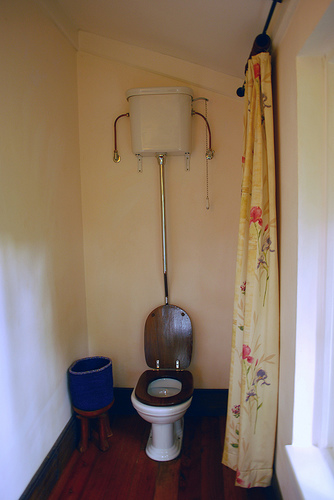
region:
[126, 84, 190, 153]
Toilet over head box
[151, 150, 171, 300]
Pipe connecting to toilet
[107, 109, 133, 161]
Pipes connecting to reservoir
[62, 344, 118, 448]
A stool with blue thing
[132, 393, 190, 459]
White porcelain toilet base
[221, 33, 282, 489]
A long yellow curtain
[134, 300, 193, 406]
A wooden toilet seat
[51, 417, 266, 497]
Hard wood bath room floor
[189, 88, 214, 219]
Flushing mechanism for toilet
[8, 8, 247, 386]
White wall of bathroom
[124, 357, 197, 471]
This is a toilet seat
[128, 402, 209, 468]
This is a toilet seat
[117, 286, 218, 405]
This is a toilet seat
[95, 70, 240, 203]
This is a toilet cistern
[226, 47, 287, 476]
This is a curtain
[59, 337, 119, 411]
This is a bucket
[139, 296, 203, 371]
This is a wooden cover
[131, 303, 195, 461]
a toilet with a wooden toilet seat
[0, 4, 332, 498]
a small bathroom area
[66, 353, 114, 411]
a blue wastepaper basket sitting on a stool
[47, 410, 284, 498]
a wooden floor of a bathroom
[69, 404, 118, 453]
a small wooden stool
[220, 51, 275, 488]
a pretty flowered shower curtain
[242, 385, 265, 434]
a blue flower on a shower curtain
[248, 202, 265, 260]
a pink flower on a shower curtain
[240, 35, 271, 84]
wooden shower curtain rings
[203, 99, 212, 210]
a chain toilet flusher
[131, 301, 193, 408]
the toilet seat is wooden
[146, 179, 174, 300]
the pipe is metal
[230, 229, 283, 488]
the curtain is hanging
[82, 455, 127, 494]
the floor is made of wood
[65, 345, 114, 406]
the bucket is blue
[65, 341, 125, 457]
the bucket is on a stool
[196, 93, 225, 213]
the cord is hanging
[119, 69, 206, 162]
the tank is above the toilet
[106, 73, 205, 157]
the tank is white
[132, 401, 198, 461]
the toilet is white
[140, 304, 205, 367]
wooden toilet lid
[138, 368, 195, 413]
wooden toilet seat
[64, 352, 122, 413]
blue basket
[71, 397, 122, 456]
wooden stool with legs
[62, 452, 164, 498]
wooden floor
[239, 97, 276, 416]
yellow shower curtain with flowers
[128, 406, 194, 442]
white toilet bowl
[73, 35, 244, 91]
white wall trim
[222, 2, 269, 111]
black curtain rod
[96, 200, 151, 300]
peach colored wall